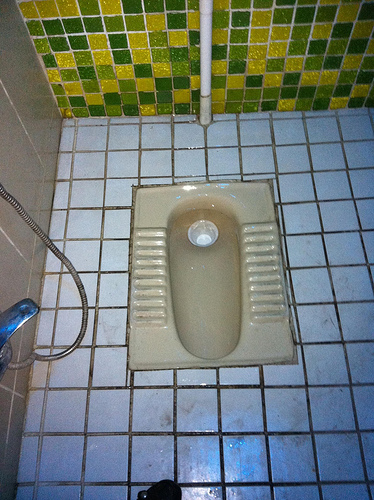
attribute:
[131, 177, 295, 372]
urinal — ridged, gray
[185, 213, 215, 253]
center — oval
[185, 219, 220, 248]
hole — small, brown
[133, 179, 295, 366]
drain — large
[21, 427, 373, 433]
grout — dark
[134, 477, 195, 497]
object — black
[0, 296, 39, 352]
handle — metal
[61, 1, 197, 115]
tiles — mismatched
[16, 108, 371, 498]
tiles — small, white, square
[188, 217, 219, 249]
drain — white, plastic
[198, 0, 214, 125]
pipe — white, pvc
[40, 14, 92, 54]
tiles — dark, green, wall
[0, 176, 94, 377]
hose — metal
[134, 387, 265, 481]
tile — dirty, white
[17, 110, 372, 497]
floor — very dirty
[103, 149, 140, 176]
tile — large, brown, shiny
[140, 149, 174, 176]
tile — large, brown, shiny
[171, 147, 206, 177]
tile — large, brown, shiny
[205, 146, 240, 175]
tile — large, brown, shiny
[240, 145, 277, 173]
tile — large, brown, shiny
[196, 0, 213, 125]
pole — skinny, white, pvc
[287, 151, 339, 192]
tiles — wet, grimy, square, floor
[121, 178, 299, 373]
toilet — beige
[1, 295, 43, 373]
faucet — small, silver